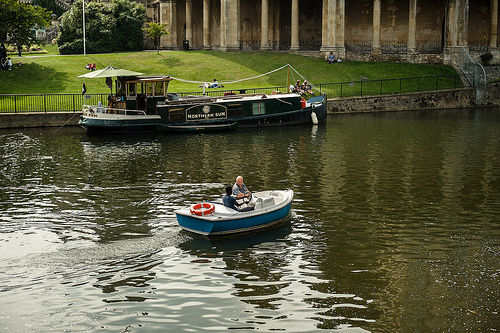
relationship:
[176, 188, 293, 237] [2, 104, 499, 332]
boat on water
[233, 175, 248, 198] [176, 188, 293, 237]
passenger in a boat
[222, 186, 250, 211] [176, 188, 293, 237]
passenger in a boat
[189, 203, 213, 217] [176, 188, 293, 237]
lifesaver on a boat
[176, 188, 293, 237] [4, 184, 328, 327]
boat has caused river wake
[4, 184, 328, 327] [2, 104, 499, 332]
wake in river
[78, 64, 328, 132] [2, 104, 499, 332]
boat on river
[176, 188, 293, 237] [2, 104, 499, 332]
boat on river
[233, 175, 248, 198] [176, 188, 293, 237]
tourist on boat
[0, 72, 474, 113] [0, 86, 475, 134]
rail on sidewalk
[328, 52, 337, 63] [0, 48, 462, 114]
person resting in grass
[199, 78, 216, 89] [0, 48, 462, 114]
person resting in grass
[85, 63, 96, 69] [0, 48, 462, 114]
person resting in grass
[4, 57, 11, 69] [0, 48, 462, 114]
person resting in grass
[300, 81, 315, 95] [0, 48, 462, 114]
person resting in grass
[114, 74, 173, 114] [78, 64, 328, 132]
cabin on boat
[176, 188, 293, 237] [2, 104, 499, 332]
motorboat on water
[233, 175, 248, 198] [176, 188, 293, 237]
person sitting on a boat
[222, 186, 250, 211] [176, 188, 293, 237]
person sitting on a boat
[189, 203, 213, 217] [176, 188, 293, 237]
device on back of th boat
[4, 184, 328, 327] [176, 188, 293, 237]
ripples are made by boat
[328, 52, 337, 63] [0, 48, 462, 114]
person sitting on grass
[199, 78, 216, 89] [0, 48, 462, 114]
person sitting on grass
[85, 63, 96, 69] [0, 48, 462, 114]
person sitting on grass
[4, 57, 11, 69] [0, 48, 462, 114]
person sitting on grass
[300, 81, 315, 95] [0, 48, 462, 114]
person sitting on grass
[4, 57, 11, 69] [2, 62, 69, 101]
person sitting in shade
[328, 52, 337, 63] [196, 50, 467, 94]
person sitting in shade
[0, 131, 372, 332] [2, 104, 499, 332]
reflection of light on water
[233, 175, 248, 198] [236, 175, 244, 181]
man has hair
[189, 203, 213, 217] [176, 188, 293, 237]
ring on boat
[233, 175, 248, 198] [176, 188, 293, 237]
male on boat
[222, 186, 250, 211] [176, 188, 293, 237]
male driving boat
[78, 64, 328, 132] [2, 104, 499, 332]
boat in water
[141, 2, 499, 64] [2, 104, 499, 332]
building next to pond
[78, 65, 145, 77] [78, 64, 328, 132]
umbrella on boat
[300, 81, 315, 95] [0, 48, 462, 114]
person lounging in grass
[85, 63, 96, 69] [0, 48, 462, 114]
person lounging in grass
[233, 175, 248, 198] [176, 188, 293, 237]
person seated on boat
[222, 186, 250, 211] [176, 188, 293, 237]
person seated on boat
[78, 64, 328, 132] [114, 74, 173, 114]
boat has a cabin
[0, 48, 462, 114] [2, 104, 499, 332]
grass by river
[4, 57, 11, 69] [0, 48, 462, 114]
person resting on grass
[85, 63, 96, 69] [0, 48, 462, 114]
person resting on grass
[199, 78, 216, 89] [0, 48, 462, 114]
person resting on grass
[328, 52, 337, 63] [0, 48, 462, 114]
person resting on grass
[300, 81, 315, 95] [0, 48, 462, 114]
person resting on grass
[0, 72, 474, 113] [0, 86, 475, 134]
fencing on wall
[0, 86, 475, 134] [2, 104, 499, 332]
wall by river